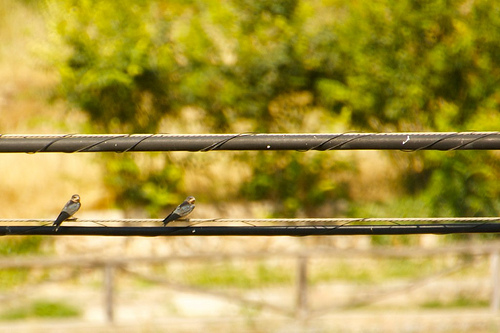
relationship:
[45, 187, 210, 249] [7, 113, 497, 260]
perched birds are on cable